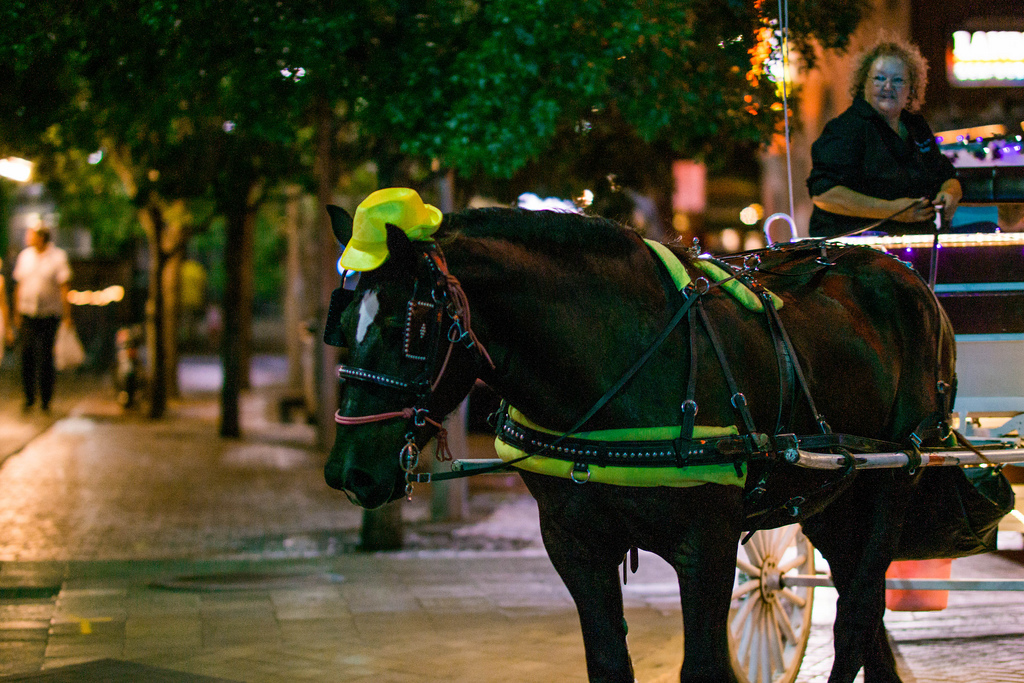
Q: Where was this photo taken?
A: At a park.